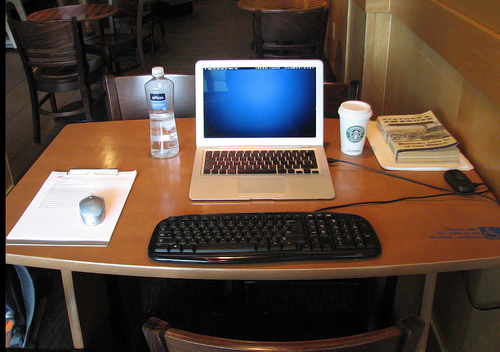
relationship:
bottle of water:
[145, 64, 181, 160] [149, 115, 179, 158]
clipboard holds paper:
[1, 165, 138, 249] [9, 170, 144, 242]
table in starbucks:
[1, 115, 500, 281] [337, 99, 375, 155]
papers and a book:
[368, 119, 471, 173] [378, 111, 460, 162]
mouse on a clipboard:
[78, 194, 108, 223] [1, 165, 138, 249]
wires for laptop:
[320, 156, 495, 212] [189, 60, 333, 199]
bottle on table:
[145, 64, 181, 160] [1, 115, 500, 281]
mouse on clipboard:
[78, 194, 108, 223] [1, 165, 138, 249]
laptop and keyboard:
[189, 60, 333, 199] [148, 210, 381, 261]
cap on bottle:
[152, 65, 169, 79] [145, 64, 181, 160]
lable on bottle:
[151, 93, 168, 111] [145, 64, 181, 160]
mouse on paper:
[78, 194, 108, 223] [9, 170, 144, 242]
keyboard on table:
[148, 210, 381, 261] [1, 115, 500, 281]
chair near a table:
[247, 8, 327, 58] [231, 2, 332, 16]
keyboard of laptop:
[202, 146, 320, 193] [189, 60, 333, 199]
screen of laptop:
[204, 71, 318, 138] [189, 60, 333, 199]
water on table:
[149, 115, 179, 158] [1, 115, 500, 281]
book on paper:
[378, 111, 460, 162] [368, 119, 471, 173]